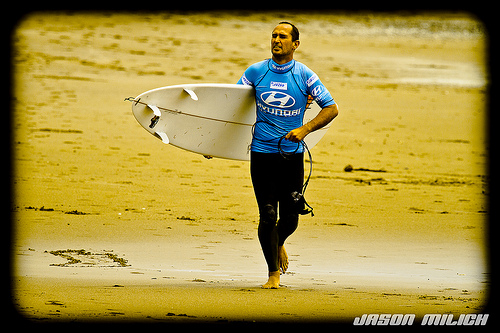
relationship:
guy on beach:
[203, 21, 339, 289] [17, 13, 483, 325]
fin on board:
[142, 75, 183, 156] [126, 47, 356, 173]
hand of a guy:
[280, 129, 306, 142] [203, 21, 339, 289]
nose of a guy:
[272, 35, 280, 45] [203, 21, 339, 289]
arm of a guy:
[302, 70, 342, 146] [203, 21, 339, 289]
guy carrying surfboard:
[233, 23, 339, 290] [127, 83, 333, 163]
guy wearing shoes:
[233, 23, 339, 290] [259, 250, 290, 290]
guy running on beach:
[203, 21, 339, 289] [17, 13, 483, 325]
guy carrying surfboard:
[203, 21, 339, 289] [127, 83, 333, 163]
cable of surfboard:
[251, 120, 316, 217] [127, 83, 333, 163]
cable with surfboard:
[251, 88, 314, 216] [127, 83, 333, 163]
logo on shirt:
[259, 88, 297, 109] [237, 15, 344, 296]